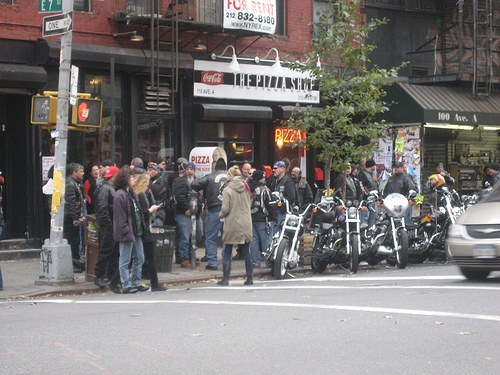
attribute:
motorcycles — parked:
[257, 186, 481, 270]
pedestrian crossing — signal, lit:
[32, 96, 57, 128]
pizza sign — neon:
[184, 144, 226, 177]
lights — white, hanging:
[217, 41, 329, 81]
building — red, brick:
[1, 0, 378, 200]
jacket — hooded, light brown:
[225, 181, 257, 243]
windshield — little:
[285, 203, 309, 223]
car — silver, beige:
[442, 172, 499, 290]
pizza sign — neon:
[269, 123, 308, 153]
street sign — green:
[34, 0, 73, 16]